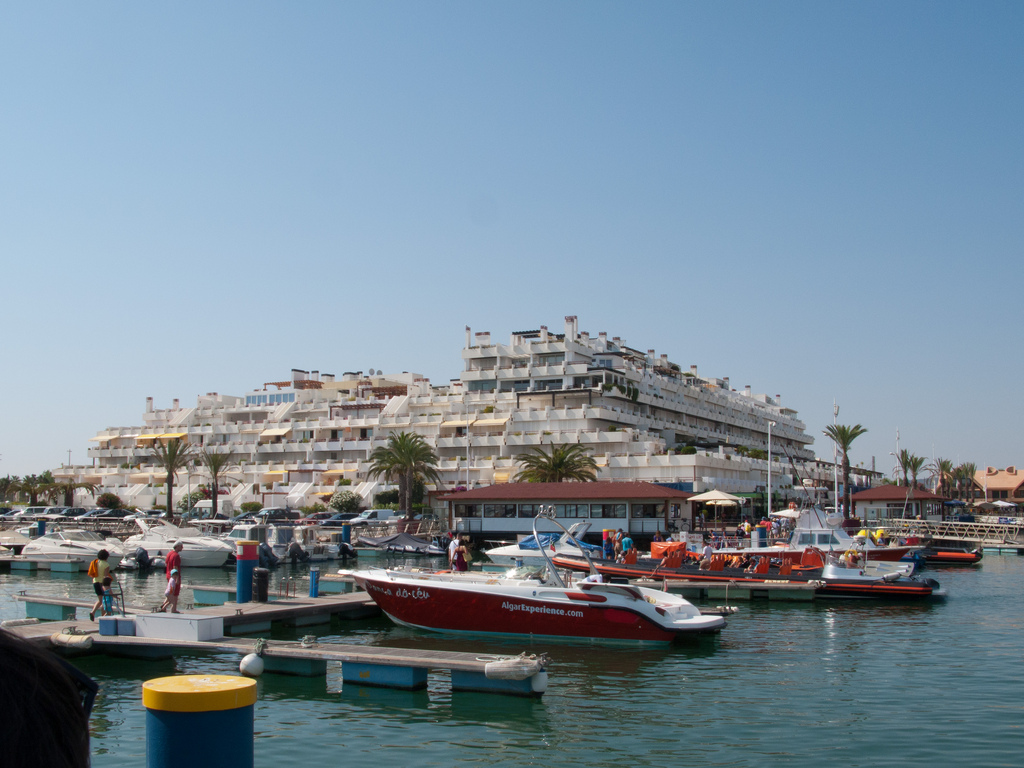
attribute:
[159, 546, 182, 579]
shirt — red 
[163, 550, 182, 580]
shirt — red 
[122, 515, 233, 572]
boat — white 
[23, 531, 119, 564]
boat — white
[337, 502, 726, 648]
boat — red , white 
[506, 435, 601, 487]
palm tree — green 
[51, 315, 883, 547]
building — white 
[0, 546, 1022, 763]
water — calm 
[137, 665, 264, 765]
post — blue , yellow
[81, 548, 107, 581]
red purse — red 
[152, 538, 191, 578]
red shirt — red 